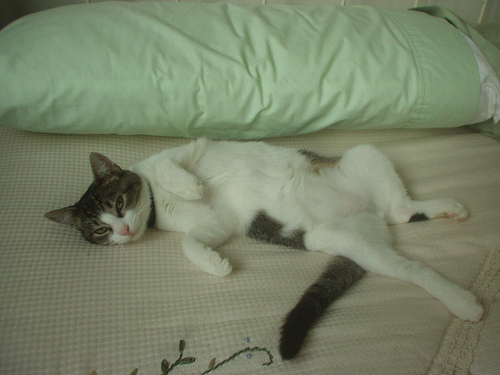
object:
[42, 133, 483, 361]
cat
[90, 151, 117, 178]
ear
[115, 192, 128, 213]
eye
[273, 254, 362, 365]
tail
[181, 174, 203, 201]
paw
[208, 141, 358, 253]
belly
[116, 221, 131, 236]
nose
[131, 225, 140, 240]
mouth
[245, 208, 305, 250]
spot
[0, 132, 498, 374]
blanket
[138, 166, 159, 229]
collar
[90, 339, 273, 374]
stitch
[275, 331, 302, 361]
tip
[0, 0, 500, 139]
pillow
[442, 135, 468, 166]
pattern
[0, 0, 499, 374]
bed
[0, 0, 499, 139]
case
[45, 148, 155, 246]
head